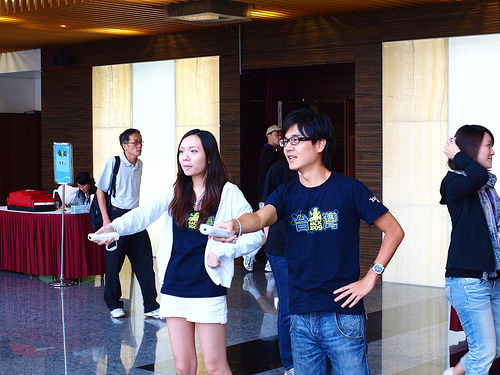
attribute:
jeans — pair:
[287, 314, 373, 374]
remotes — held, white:
[199, 223, 237, 242]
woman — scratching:
[437, 125, 499, 373]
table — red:
[2, 206, 108, 288]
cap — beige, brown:
[263, 123, 282, 134]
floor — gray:
[0, 265, 499, 374]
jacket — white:
[109, 181, 265, 295]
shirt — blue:
[264, 175, 391, 317]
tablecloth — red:
[1, 208, 106, 278]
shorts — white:
[157, 295, 231, 327]